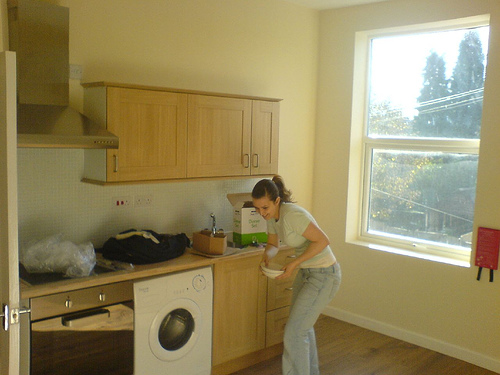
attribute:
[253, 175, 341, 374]
woman — standing, smiling, hunched over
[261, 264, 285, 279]
bowl — ceramic, white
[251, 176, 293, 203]
hair — brown, pulled back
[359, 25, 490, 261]
window — tall, large, curtainless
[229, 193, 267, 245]
box — green, white, open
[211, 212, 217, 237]
faucet — stainless steel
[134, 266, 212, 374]
washer — white, built in, new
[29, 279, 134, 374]
dishwasher — built in, stainless steel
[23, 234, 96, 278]
bag — plastic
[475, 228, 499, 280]
sign — red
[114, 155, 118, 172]
handle — silver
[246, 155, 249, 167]
handle — silver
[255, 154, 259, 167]
handle — silver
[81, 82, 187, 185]
cabinet — wood, tan, hanging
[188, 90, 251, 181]
cabinet — wood, tan, hanging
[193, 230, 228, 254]
cardboard — brown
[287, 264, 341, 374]
jeans — light blue, white wash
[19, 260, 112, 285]
stove top — stainless steel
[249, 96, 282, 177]
cabinet — wood, hanging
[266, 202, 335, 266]
shirt — cotton, white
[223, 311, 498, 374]
flooring — hardwood, stained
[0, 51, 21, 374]
door — white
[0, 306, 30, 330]
handle — metal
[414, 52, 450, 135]
tree — tall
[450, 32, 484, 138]
tree — tall